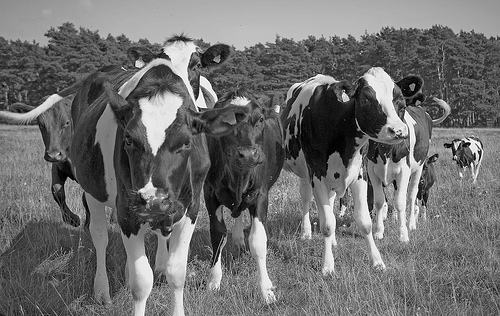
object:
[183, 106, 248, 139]
ear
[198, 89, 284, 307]
cow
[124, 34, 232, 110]
cow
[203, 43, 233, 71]
ear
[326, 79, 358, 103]
ear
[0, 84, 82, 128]
tail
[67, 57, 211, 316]
cow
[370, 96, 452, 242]
cow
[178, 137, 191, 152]
eye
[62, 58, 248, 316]
cow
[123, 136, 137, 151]
eye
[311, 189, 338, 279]
leg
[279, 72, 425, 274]
cow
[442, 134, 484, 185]
cow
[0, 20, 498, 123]
trees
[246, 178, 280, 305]
leg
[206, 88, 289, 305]
cow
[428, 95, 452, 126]
tail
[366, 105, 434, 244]
cow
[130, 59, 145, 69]
tag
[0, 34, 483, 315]
cows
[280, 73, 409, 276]
cow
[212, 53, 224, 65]
tag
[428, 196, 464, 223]
flowers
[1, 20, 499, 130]
forest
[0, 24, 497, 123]
background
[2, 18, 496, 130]
row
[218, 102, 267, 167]
face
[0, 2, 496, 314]
photo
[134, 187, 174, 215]
nose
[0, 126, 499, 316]
grass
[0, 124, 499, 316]
ground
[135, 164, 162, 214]
spot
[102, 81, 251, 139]
ears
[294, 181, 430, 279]
legs